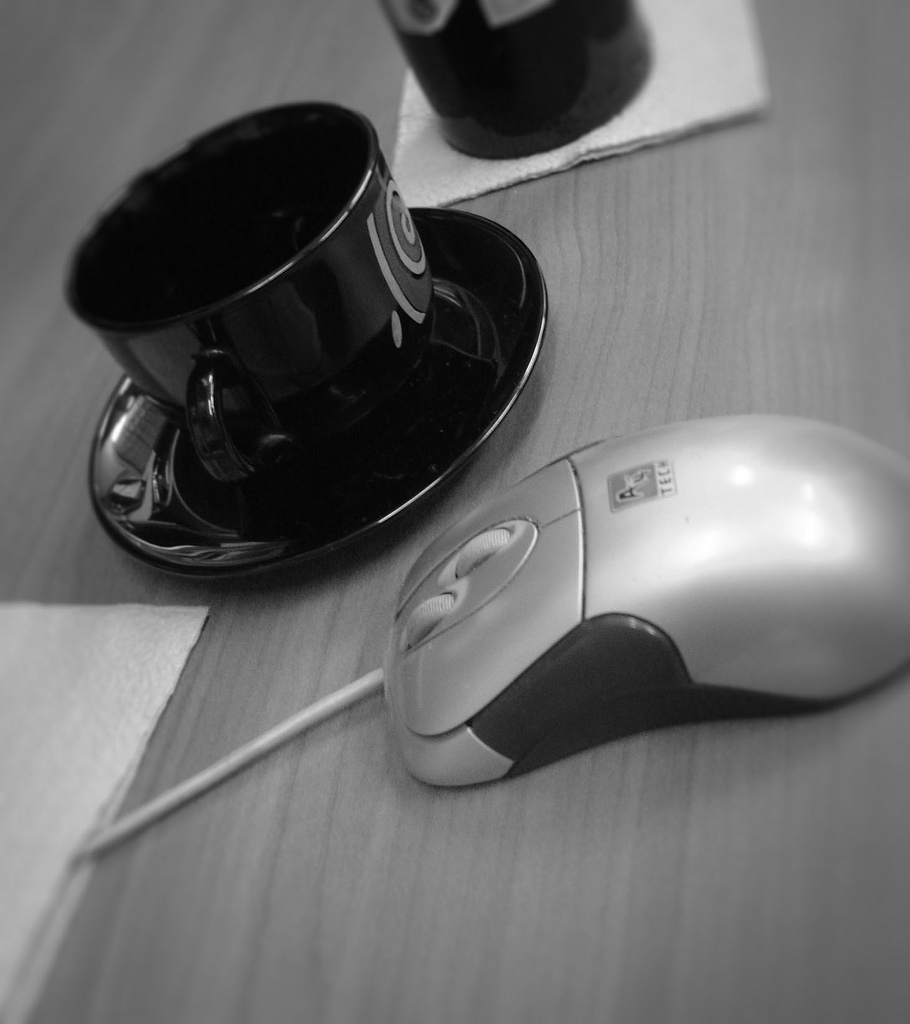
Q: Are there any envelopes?
A: No, there are no envelopes.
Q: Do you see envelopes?
A: No, there are no envelopes.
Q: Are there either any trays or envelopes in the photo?
A: No, there are no envelopes or trays.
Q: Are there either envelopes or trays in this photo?
A: No, there are no envelopes or trays.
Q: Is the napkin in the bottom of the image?
A: No, the napkin is in the top of the image.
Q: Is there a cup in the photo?
A: Yes, there is a cup.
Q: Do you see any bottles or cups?
A: Yes, there is a cup.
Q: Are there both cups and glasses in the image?
A: No, there is a cup but no glasses.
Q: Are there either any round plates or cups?
A: Yes, there is a round cup.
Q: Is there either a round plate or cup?
A: Yes, there is a round cup.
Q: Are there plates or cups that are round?
A: Yes, the cup is round.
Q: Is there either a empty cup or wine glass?
A: Yes, there is an empty cup.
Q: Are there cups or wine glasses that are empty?
A: Yes, the cup is empty.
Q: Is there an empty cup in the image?
A: Yes, there is an empty cup.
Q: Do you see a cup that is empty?
A: Yes, there is a cup that is empty.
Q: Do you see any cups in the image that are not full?
A: Yes, there is a empty cup.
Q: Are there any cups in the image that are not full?
A: Yes, there is a empty cup.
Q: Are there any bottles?
A: No, there are no bottles.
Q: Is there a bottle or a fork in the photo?
A: No, there are no bottles or forks.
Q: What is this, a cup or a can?
A: This is a cup.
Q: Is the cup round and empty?
A: Yes, the cup is round and empty.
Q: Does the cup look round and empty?
A: Yes, the cup is round and empty.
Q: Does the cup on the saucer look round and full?
A: No, the cup is round but empty.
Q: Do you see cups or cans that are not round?
A: No, there is a cup but it is round.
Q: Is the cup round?
A: Yes, the cup is round.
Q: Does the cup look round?
A: Yes, the cup is round.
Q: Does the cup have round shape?
A: Yes, the cup is round.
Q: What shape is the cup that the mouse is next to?
A: The cup is round.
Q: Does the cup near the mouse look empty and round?
A: Yes, the cup is empty and round.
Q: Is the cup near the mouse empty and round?
A: Yes, the cup is empty and round.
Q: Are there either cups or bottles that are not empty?
A: No, there is a cup but it is empty.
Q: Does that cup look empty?
A: Yes, the cup is empty.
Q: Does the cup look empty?
A: Yes, the cup is empty.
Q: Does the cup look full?
A: No, the cup is empty.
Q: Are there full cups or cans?
A: No, there is a cup but it is empty.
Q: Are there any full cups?
A: No, there is a cup but it is empty.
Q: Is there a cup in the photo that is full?
A: No, there is a cup but it is empty.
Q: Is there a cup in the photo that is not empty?
A: No, there is a cup but it is empty.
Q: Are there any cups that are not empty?
A: No, there is a cup but it is empty.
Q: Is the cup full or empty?
A: The cup is empty.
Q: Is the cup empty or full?
A: The cup is empty.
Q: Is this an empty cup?
A: Yes, this is an empty cup.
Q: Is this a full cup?
A: No, this is an empty cup.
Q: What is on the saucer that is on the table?
A: The cup is on the saucer.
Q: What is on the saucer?
A: The cup is on the saucer.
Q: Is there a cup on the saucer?
A: Yes, there is a cup on the saucer.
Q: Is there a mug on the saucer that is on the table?
A: No, there is a cup on the saucer.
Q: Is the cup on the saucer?
A: Yes, the cup is on the saucer.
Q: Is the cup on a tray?
A: No, the cup is on the saucer.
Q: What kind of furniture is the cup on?
A: The cup is on the table.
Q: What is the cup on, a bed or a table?
A: The cup is on a table.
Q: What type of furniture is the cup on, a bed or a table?
A: The cup is on a table.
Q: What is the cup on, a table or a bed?
A: The cup is on a table.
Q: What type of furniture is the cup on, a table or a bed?
A: The cup is on a table.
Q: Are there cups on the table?
A: Yes, there is a cup on the table.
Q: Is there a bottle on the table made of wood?
A: No, there is a cup on the table.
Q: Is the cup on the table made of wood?
A: Yes, the cup is on the table.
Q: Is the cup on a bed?
A: No, the cup is on the table.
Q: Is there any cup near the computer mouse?
A: Yes, there is a cup near the computer mouse.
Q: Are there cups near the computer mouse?
A: Yes, there is a cup near the computer mouse.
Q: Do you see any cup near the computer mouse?
A: Yes, there is a cup near the computer mouse.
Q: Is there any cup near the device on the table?
A: Yes, there is a cup near the computer mouse.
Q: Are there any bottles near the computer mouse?
A: No, there is a cup near the computer mouse.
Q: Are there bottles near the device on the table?
A: No, there is a cup near the computer mouse.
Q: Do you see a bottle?
A: No, there are no bottles.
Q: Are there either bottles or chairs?
A: No, there are no bottles or chairs.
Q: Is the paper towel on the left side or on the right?
A: The paper towel is on the left of the image.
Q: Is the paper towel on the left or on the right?
A: The paper towel is on the left of the image.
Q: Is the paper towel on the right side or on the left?
A: The paper towel is on the left of the image.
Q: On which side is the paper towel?
A: The paper towel is on the left of the image.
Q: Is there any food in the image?
A: No, there is no food.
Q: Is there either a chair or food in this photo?
A: No, there are no food or chairs.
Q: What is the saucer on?
A: The saucer is on the table.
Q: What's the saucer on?
A: The saucer is on the table.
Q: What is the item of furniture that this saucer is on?
A: The piece of furniture is a table.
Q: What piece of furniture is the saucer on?
A: The saucer is on the table.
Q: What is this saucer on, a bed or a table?
A: The saucer is on a table.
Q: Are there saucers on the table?
A: Yes, there is a saucer on the table.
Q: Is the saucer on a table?
A: Yes, the saucer is on a table.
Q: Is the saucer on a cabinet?
A: No, the saucer is on a table.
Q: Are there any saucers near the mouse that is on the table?
A: Yes, there is a saucer near the mouse.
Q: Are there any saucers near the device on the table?
A: Yes, there is a saucer near the mouse.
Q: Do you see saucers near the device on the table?
A: Yes, there is a saucer near the mouse.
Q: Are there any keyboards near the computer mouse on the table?
A: No, there is a saucer near the mouse.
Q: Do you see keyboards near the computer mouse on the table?
A: No, there is a saucer near the mouse.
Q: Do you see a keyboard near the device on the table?
A: No, there is a saucer near the mouse.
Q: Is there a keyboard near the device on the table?
A: No, there is a saucer near the mouse.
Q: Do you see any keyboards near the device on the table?
A: No, there is a saucer near the mouse.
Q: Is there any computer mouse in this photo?
A: Yes, there is a computer mouse.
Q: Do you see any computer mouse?
A: Yes, there is a computer mouse.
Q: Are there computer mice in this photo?
A: Yes, there is a computer mouse.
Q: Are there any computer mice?
A: Yes, there is a computer mouse.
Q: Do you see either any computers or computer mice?
A: Yes, there is a computer mouse.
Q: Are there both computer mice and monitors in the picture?
A: No, there is a computer mouse but no monitors.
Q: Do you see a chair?
A: No, there are no chairs.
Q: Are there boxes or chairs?
A: No, there are no chairs or boxes.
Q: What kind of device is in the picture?
A: The device is a computer mouse.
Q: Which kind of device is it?
A: The device is a computer mouse.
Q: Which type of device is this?
A: This is a computer mouse.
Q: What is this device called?
A: This is a computer mouse.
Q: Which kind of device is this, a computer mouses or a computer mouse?
A: This is a computer mouse.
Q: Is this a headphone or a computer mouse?
A: This is a computer mouse.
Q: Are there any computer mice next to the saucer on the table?
A: Yes, there is a computer mouse next to the saucer.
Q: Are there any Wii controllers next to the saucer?
A: No, there is a computer mouse next to the saucer.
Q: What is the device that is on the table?
A: The device is a computer mouse.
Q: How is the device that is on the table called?
A: The device is a computer mouse.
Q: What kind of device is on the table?
A: The device is a computer mouse.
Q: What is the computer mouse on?
A: The computer mouse is on the table.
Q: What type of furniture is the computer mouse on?
A: The computer mouse is on the table.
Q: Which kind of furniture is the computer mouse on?
A: The computer mouse is on the table.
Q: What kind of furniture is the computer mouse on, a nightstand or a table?
A: The computer mouse is on a table.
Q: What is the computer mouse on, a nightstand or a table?
A: The computer mouse is on a table.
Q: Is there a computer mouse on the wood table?
A: Yes, there is a computer mouse on the table.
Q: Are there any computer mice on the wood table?
A: Yes, there is a computer mouse on the table.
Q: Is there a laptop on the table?
A: No, there is a computer mouse on the table.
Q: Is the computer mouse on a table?
A: Yes, the computer mouse is on a table.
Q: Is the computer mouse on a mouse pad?
A: No, the computer mouse is on a table.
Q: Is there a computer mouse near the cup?
A: Yes, there is a computer mouse near the cup.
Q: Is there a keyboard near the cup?
A: No, there is a computer mouse near the cup.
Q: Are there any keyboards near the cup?
A: No, there is a computer mouse near the cup.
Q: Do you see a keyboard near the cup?
A: No, there is a computer mouse near the cup.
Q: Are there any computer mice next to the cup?
A: Yes, there is a computer mouse next to the cup.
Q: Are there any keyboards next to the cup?
A: No, there is a computer mouse next to the cup.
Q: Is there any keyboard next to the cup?
A: No, there is a computer mouse next to the cup.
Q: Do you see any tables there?
A: Yes, there is a table.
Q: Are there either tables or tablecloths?
A: Yes, there is a table.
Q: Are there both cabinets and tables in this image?
A: No, there is a table but no cabinets.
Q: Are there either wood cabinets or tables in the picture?
A: Yes, there is a wood table.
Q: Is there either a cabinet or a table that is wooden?
A: Yes, the table is wooden.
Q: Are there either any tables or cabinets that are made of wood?
A: Yes, the table is made of wood.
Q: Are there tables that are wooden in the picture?
A: Yes, there is a wood table.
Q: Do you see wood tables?
A: Yes, there is a wood table.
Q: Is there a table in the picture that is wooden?
A: Yes, there is a table that is wooden.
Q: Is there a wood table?
A: Yes, there is a table that is made of wood.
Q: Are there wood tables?
A: Yes, there is a table that is made of wood.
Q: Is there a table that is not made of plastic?
A: Yes, there is a table that is made of wood.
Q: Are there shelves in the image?
A: No, there are no shelves.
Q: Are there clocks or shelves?
A: No, there are no shelves or clocks.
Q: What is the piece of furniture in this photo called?
A: The piece of furniture is a table.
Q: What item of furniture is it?
A: The piece of furniture is a table.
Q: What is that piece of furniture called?
A: This is a table.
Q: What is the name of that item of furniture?
A: This is a table.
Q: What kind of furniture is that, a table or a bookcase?
A: This is a table.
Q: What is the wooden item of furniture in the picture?
A: The piece of furniture is a table.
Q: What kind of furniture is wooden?
A: The furniture is a table.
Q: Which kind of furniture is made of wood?
A: The furniture is a table.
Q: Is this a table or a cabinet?
A: This is a table.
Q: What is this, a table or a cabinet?
A: This is a table.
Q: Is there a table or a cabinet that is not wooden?
A: No, there is a table but it is wooden.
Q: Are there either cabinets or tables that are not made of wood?
A: No, there is a table but it is made of wood.